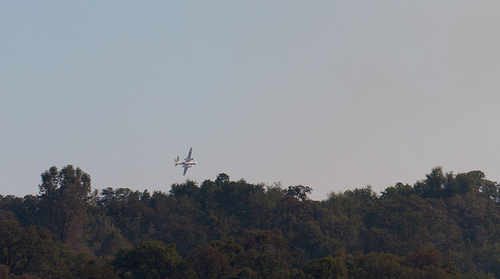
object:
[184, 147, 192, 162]
left wing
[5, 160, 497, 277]
trees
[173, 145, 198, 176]
plane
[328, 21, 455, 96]
clouds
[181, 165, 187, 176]
right wing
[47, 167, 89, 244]
tree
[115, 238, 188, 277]
tree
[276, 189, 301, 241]
tree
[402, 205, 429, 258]
tree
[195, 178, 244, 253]
tree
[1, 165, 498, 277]
forest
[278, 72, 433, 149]
skies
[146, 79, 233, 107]
cloud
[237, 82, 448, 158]
clouds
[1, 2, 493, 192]
sky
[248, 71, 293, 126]
clouds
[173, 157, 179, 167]
tail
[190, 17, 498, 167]
clouds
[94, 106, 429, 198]
sky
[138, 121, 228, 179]
air